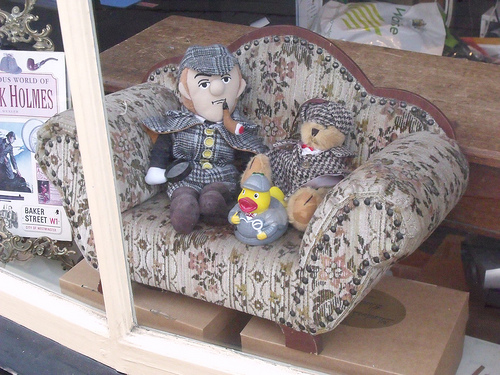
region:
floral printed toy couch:
[118, 50, 458, 310]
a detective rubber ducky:
[226, 182, 279, 258]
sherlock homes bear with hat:
[272, 85, 348, 280]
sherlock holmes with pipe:
[168, 67, 238, 210]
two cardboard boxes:
[183, 300, 311, 353]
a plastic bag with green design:
[328, 0, 464, 65]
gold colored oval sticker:
[328, 280, 406, 331]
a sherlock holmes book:
[13, 46, 103, 287]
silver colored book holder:
[2, 45, 79, 261]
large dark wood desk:
[389, 57, 485, 225]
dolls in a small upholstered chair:
[39, 24, 471, 354]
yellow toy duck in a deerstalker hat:
[228, 172, 288, 247]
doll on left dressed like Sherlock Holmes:
[139, 44, 246, 231]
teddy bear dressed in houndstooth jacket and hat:
[239, 102, 351, 231]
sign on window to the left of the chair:
[1, 52, 68, 240]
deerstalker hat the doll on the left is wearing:
[172, 43, 237, 77]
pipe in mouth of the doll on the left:
[222, 101, 244, 138]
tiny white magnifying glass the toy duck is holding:
[252, 217, 264, 241]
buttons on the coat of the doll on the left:
[203, 126, 215, 169]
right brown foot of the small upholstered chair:
[284, 326, 322, 354]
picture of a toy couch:
[20, 15, 449, 295]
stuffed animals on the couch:
[135, 46, 366, 238]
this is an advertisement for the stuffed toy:
[0, 43, 70, 263]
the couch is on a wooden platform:
[34, 47, 474, 338]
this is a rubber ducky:
[208, 165, 307, 257]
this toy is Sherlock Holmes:
[125, 48, 244, 243]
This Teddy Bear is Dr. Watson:
[241, 101, 363, 191]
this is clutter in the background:
[291, 1, 498, 67]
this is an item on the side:
[420, 219, 498, 344]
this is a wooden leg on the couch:
[245, 287, 339, 368]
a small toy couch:
[40, 24, 470, 356]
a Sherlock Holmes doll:
[157, 43, 258, 237]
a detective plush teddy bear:
[262, 100, 352, 226]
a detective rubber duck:
[223, 173, 289, 246]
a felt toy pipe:
[217, 100, 242, 136]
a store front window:
[2, 0, 495, 374]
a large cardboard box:
[240, 255, 471, 372]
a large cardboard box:
[56, 248, 251, 354]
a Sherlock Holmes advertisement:
[1, 51, 63, 236]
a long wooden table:
[105, 9, 496, 240]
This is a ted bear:
[153, 28, 245, 131]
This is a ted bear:
[286, 97, 354, 165]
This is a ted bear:
[151, 37, 253, 245]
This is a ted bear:
[245, 63, 361, 248]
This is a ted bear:
[220, 149, 287, 251]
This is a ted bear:
[0, 128, 32, 183]